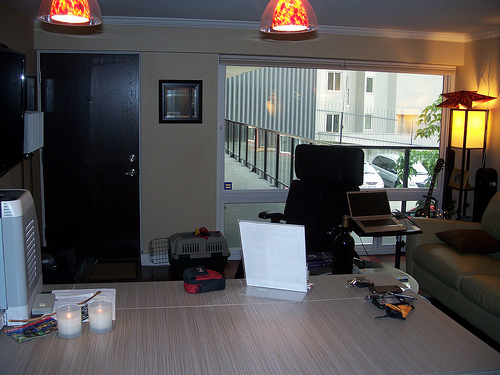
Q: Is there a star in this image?
A: Yes, there is a star.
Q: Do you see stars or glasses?
A: Yes, there is a star.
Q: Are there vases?
A: No, there are no vases.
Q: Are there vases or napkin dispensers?
A: No, there are no vases or napkin dispensers.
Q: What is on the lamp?
A: The star is on the lamp.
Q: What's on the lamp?
A: The star is on the lamp.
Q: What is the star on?
A: The star is on the lamp.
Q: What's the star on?
A: The star is on the lamp.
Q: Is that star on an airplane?
A: No, the star is on a lamp.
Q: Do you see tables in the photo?
A: Yes, there is a table.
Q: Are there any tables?
A: Yes, there is a table.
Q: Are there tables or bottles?
A: Yes, there is a table.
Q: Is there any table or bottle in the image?
A: Yes, there is a table.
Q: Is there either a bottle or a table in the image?
A: Yes, there is a table.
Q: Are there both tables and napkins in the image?
A: No, there is a table but no napkins.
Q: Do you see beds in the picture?
A: No, there are no beds.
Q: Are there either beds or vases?
A: No, there are no beds or vases.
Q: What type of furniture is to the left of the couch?
A: The piece of furniture is a table.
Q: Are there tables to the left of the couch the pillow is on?
A: Yes, there is a table to the left of the couch.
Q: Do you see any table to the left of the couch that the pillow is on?
A: Yes, there is a table to the left of the couch.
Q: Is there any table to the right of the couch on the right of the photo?
A: No, the table is to the left of the couch.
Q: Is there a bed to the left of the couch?
A: No, there is a table to the left of the couch.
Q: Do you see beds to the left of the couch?
A: No, there is a table to the left of the couch.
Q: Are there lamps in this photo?
A: Yes, there is a lamp.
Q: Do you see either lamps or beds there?
A: Yes, there is a lamp.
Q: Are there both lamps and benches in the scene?
A: No, there is a lamp but no benches.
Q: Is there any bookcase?
A: No, there are no bookcases.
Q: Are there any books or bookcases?
A: No, there are no bookcases or books.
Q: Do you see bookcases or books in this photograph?
A: No, there are no bookcases or books.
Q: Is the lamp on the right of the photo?
A: Yes, the lamp is on the right of the image.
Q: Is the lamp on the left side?
A: No, the lamp is on the right of the image.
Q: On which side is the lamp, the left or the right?
A: The lamp is on the right of the image.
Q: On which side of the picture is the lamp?
A: The lamp is on the right of the image.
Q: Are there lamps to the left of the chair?
A: No, the lamp is to the right of the chair.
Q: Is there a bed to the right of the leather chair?
A: No, there is a lamp to the right of the chair.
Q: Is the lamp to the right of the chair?
A: Yes, the lamp is to the right of the chair.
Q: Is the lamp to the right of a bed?
A: No, the lamp is to the right of the chair.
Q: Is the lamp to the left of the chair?
A: No, the lamp is to the right of the chair.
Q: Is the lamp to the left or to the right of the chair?
A: The lamp is to the right of the chair.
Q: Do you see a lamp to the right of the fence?
A: Yes, there is a lamp to the right of the fence.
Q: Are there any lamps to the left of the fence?
A: No, the lamp is to the right of the fence.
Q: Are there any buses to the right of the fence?
A: No, there is a lamp to the right of the fence.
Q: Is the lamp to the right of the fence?
A: Yes, the lamp is to the right of the fence.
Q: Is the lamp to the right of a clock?
A: No, the lamp is to the right of the fence.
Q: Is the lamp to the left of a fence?
A: No, the lamp is to the right of a fence.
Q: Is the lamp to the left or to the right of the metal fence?
A: The lamp is to the right of the fence.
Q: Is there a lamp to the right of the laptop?
A: Yes, there is a lamp to the right of the laptop.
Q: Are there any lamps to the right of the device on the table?
A: Yes, there is a lamp to the right of the laptop.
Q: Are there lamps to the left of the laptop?
A: No, the lamp is to the right of the laptop.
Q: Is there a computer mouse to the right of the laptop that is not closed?
A: No, there is a lamp to the right of the laptop.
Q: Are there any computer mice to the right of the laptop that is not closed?
A: No, there is a lamp to the right of the laptop.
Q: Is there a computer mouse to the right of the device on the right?
A: No, there is a lamp to the right of the laptop.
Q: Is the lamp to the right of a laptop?
A: Yes, the lamp is to the right of a laptop.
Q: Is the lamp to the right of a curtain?
A: No, the lamp is to the right of a laptop.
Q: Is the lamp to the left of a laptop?
A: No, the lamp is to the right of a laptop.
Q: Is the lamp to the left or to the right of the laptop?
A: The lamp is to the right of the laptop.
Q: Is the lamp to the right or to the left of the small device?
A: The lamp is to the right of the laptop.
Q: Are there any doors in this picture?
A: Yes, there is a door.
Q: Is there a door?
A: Yes, there is a door.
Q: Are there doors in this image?
A: Yes, there is a door.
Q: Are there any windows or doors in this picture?
A: Yes, there is a door.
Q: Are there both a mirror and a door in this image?
A: Yes, there are both a door and a mirror.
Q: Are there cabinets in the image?
A: No, there are no cabinets.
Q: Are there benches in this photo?
A: No, there are no benches.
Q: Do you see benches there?
A: No, there are no benches.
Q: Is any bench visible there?
A: No, there are no benches.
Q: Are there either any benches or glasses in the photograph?
A: No, there are no benches or glasses.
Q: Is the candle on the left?
A: Yes, the candle is on the left of the image.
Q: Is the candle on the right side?
A: No, the candle is on the left of the image.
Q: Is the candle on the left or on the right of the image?
A: The candle is on the left of the image.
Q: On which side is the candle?
A: The candle is on the left of the image.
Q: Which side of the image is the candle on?
A: The candle is on the left of the image.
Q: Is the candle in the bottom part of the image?
A: Yes, the candle is in the bottom of the image.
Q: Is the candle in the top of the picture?
A: No, the candle is in the bottom of the image.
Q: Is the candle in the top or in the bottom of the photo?
A: The candle is in the bottom of the image.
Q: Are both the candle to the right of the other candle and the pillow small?
A: Yes, both the candle and the pillow are small.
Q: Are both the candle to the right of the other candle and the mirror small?
A: Yes, both the candle and the mirror are small.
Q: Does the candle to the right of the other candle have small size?
A: Yes, the candle is small.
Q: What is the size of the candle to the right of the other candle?
A: The candle is small.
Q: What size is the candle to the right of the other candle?
A: The candle is small.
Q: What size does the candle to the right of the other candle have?
A: The candle has small size.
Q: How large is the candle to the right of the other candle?
A: The candle is small.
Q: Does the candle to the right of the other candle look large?
A: No, the candle is small.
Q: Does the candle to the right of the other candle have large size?
A: No, the candle is small.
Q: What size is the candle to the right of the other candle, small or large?
A: The candle is small.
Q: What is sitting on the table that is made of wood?
A: The candle is sitting on the table.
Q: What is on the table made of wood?
A: The candle is on the table.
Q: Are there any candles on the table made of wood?
A: Yes, there is a candle on the table.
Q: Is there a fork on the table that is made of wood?
A: No, there is a candle on the table.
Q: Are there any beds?
A: No, there are no beds.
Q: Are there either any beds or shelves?
A: No, there are no beds or shelves.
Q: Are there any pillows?
A: Yes, there is a pillow.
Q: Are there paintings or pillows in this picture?
A: Yes, there is a pillow.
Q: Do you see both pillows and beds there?
A: No, there is a pillow but no beds.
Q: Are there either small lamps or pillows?
A: Yes, there is a small pillow.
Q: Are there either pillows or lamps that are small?
A: Yes, the pillow is small.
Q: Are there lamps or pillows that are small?
A: Yes, the pillow is small.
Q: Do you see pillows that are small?
A: Yes, there is a small pillow.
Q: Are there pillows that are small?
A: Yes, there is a pillow that is small.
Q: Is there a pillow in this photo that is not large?
A: Yes, there is a small pillow.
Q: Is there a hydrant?
A: No, there are no fire hydrants.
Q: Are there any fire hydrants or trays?
A: No, there are no fire hydrants or trays.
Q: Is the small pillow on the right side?
A: Yes, the pillow is on the right of the image.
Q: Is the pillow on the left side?
A: No, the pillow is on the right of the image.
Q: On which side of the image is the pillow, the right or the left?
A: The pillow is on the right of the image.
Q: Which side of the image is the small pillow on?
A: The pillow is on the right of the image.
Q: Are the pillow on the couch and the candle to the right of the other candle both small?
A: Yes, both the pillow and the candle are small.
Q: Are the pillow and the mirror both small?
A: Yes, both the pillow and the mirror are small.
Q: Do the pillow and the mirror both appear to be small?
A: Yes, both the pillow and the mirror are small.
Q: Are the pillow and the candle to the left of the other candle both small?
A: Yes, both the pillow and the candle are small.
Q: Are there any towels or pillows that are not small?
A: No, there is a pillow but it is small.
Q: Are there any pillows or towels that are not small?
A: No, there is a pillow but it is small.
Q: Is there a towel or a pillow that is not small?
A: No, there is a pillow but it is small.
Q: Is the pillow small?
A: Yes, the pillow is small.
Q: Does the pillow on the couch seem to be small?
A: Yes, the pillow is small.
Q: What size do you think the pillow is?
A: The pillow is small.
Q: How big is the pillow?
A: The pillow is small.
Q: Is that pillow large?
A: No, the pillow is small.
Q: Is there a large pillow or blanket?
A: No, there is a pillow but it is small.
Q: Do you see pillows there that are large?
A: No, there is a pillow but it is small.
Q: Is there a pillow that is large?
A: No, there is a pillow but it is small.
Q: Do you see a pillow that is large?
A: No, there is a pillow but it is small.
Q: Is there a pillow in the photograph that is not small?
A: No, there is a pillow but it is small.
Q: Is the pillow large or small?
A: The pillow is small.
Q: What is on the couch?
A: The pillow is on the couch.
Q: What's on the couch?
A: The pillow is on the couch.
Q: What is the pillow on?
A: The pillow is on the couch.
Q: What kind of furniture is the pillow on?
A: The pillow is on the couch.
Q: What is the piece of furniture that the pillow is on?
A: The piece of furniture is a couch.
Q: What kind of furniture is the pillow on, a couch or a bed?
A: The pillow is on a couch.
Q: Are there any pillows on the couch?
A: Yes, there is a pillow on the couch.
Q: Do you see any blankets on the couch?
A: No, there is a pillow on the couch.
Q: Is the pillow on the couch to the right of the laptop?
A: Yes, the pillow is on the couch.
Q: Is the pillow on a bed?
A: No, the pillow is on the couch.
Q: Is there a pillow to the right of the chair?
A: Yes, there is a pillow to the right of the chair.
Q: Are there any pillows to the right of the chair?
A: Yes, there is a pillow to the right of the chair.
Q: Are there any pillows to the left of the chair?
A: No, the pillow is to the right of the chair.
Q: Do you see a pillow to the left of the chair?
A: No, the pillow is to the right of the chair.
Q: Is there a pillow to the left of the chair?
A: No, the pillow is to the right of the chair.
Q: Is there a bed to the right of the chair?
A: No, there is a pillow to the right of the chair.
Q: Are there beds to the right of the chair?
A: No, there is a pillow to the right of the chair.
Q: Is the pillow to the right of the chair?
A: Yes, the pillow is to the right of the chair.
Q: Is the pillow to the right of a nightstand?
A: No, the pillow is to the right of the chair.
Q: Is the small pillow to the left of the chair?
A: No, the pillow is to the right of the chair.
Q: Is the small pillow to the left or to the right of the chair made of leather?
A: The pillow is to the right of the chair.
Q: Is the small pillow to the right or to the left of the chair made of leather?
A: The pillow is to the right of the chair.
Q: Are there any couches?
A: Yes, there is a couch.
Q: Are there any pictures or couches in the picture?
A: Yes, there is a couch.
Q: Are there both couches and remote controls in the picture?
A: No, there is a couch but no remote controls.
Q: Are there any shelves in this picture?
A: No, there are no shelves.